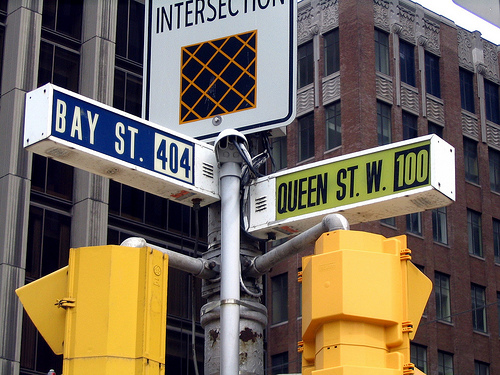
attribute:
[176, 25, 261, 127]
grid — blue, orange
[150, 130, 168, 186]
number 4 — blue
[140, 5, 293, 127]
sign — yellow, white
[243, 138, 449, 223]
street sign — yellow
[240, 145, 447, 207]
sign — street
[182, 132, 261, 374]
pole — large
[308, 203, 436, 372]
signal — yellow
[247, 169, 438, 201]
sign — white, rectanguar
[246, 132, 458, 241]
sign — white, green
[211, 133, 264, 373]
pole — small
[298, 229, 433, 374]
street light — yellow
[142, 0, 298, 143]
sign — traffic, saying intersection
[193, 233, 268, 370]
pole — rusty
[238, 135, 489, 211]
sign — green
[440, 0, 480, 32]
sky — between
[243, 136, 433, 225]
sign — yellow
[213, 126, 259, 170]
conduit — electrical, weatherproof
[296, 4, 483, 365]
building — red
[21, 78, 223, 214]
sign — electric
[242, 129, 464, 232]
street sign — yellow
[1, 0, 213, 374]
building — black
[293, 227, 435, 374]
traffic light — yellow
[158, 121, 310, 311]
pipe fitting — 90 degrees